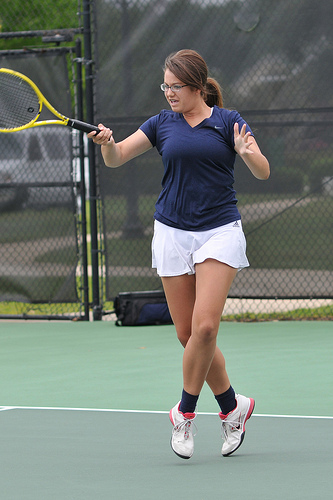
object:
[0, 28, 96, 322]
gate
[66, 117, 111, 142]
handle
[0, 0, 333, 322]
fence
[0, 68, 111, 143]
racket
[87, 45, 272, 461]
girl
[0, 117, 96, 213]
vehicle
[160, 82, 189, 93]
glasses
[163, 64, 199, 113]
face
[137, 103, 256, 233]
shirt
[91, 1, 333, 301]
wall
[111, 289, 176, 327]
bag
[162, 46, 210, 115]
head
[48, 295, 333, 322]
sidewalk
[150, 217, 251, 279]
shorts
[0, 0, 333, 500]
court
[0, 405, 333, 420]
line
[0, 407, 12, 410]
line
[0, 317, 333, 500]
ground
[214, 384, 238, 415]
sock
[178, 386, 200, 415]
sock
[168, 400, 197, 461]
shoe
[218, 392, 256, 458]
shoe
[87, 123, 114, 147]
hand